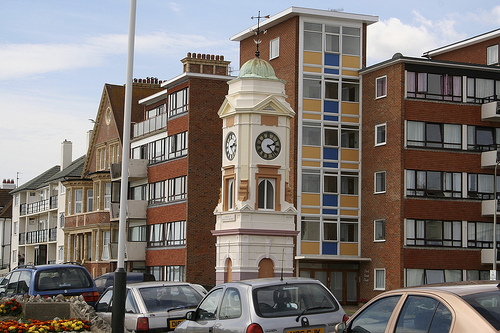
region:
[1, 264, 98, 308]
blue van parked on side of road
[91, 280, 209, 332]
small silver car parked on side of road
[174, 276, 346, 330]
small silver car parked on side of road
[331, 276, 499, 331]
beige car parked on side of road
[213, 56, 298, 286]
tall white clock tower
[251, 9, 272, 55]
weather vane atop clock tower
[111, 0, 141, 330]
tall thin white pole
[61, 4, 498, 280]
tall brick building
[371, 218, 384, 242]
window on brick building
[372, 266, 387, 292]
window on brick building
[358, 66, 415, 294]
The building is made of bricks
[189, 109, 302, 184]
The building has 2 clocks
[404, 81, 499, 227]
The windows have curtains in them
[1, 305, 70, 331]
The flowers are orange and yellow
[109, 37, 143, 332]
The pole is made of metal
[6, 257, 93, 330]
The van is blue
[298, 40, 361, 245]
The building has many windows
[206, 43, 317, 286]
The building has a rounded top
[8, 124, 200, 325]
More buildings are in the back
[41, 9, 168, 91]
The sky is blue and cloudy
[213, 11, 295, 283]
a clock tower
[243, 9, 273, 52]
a weather vane at the top of the clock tower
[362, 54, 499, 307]
a brick apartment building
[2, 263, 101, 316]
a blue minivan parked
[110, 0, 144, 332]
a tall white pole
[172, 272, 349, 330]
a silver 2-door car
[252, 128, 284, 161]
a large clockface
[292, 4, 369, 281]
a blue and orange building facade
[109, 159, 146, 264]
large balconies extending from building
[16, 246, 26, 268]
a person on a balcony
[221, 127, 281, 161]
two black and white clocks on stone tower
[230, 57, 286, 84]
green dome on top of tall stone tower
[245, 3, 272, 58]
metal weather vane on top of green dome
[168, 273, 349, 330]
two door silver hatchback parked next to sidewalk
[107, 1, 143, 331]
tall metal pole on sidewalk with green base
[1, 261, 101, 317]
blue van parked next to sidewalk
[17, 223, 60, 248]
balcony on building with black fence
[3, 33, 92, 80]
white cloud in blue sky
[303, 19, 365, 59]
three windows on side of buiding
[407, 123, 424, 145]
white curtain in window of building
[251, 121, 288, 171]
white clock with black hands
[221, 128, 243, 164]
white clock with black hands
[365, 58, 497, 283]
multilevel red brick building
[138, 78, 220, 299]
multilevel red brick building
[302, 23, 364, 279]
multilevel building with blue and yellow details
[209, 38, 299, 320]
decorative clock tower in city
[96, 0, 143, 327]
bottom of metal flag pole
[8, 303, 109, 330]
red and yellow flowers in garden beside street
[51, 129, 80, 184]
chimney to white brick building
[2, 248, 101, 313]
blue mini van parked on street